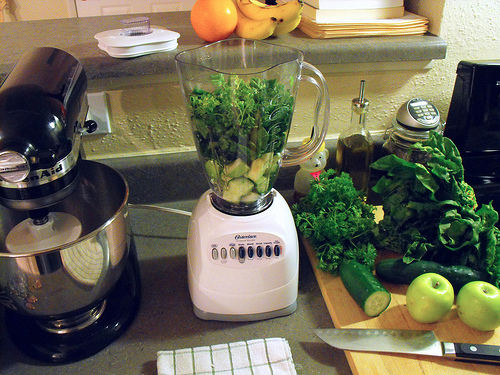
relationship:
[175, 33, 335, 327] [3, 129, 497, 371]
blender on counter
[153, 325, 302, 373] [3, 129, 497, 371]
cloth on counter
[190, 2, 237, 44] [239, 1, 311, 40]
orange beside bananas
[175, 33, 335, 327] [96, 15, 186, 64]
blender has lid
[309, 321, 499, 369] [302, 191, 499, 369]
knife on board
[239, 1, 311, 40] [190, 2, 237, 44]
bananas are beside orange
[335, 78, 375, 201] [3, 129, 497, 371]
bottle on counter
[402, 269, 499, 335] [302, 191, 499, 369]
apples are on board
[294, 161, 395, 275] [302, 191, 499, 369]
leaves are on board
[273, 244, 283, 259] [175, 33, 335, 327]
button on blender